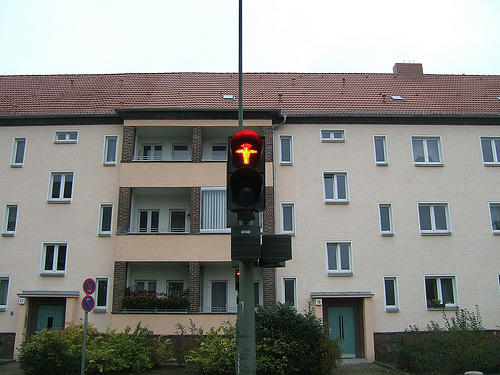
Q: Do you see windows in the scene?
A: Yes, there is a window.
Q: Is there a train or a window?
A: Yes, there is a window.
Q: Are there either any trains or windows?
A: Yes, there is a window.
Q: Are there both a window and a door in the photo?
A: Yes, there are both a window and a door.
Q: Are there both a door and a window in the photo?
A: Yes, there are both a window and a door.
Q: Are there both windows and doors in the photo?
A: Yes, there are both a window and a door.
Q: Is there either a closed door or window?
A: Yes, there is a closed window.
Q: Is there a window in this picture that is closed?
A: Yes, there is a window that is closed.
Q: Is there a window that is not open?
A: Yes, there is an closed window.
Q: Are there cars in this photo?
A: No, there are no cars.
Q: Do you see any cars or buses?
A: No, there are no cars or buses.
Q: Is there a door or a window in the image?
A: Yes, there is a window.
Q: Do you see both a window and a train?
A: No, there is a window but no trains.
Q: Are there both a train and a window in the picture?
A: No, there is a window but no trains.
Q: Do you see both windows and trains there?
A: No, there is a window but no trains.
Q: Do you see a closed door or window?
A: Yes, there is a closed window.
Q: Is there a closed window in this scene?
A: Yes, there is a closed window.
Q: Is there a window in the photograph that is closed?
A: Yes, there is a window that is closed.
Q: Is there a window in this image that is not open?
A: Yes, there is an closed window.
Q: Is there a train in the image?
A: No, there are no trains.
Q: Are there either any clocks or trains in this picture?
A: No, there are no trains or clocks.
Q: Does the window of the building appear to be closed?
A: Yes, the window is closed.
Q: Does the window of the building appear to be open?
A: No, the window is closed.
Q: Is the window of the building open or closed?
A: The window is closed.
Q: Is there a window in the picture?
A: Yes, there is a window.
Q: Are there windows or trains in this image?
A: Yes, there is a window.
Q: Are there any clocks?
A: No, there are no clocks.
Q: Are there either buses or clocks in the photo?
A: No, there are no clocks or buses.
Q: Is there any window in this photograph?
A: Yes, there is a window.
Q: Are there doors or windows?
A: Yes, there is a window.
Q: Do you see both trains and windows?
A: No, there is a window but no trains.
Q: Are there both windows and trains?
A: No, there is a window but no trains.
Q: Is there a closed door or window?
A: Yes, there is a closed window.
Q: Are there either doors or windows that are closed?
A: Yes, the window is closed.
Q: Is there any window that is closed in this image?
A: Yes, there is a closed window.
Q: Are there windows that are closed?
A: Yes, there is a window that is closed.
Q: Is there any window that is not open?
A: Yes, there is an closed window.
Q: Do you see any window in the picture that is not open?
A: Yes, there is an closed window.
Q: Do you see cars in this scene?
A: No, there are no cars.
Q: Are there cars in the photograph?
A: No, there are no cars.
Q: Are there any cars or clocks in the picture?
A: No, there are no cars or clocks.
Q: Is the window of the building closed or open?
A: The window is closed.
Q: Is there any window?
A: Yes, there is a window.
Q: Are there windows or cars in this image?
A: Yes, there is a window.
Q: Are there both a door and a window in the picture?
A: Yes, there are both a window and a door.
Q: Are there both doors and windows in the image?
A: Yes, there are both a window and a door.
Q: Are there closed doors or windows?
A: Yes, there is a closed window.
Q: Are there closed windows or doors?
A: Yes, there is a closed window.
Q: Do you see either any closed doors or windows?
A: Yes, there is a closed window.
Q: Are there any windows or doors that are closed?
A: Yes, the window is closed.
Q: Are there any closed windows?
A: Yes, there is a closed window.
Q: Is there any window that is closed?
A: Yes, there is a window that is closed.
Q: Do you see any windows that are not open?
A: Yes, there is an closed window.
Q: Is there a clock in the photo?
A: No, there are no clocks.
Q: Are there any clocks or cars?
A: No, there are no clocks or cars.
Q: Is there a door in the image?
A: Yes, there is a door.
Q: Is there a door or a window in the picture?
A: Yes, there is a door.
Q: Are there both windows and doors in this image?
A: Yes, there are both a door and a window.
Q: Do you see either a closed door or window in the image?
A: Yes, there is a closed door.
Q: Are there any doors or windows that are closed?
A: Yes, the door is closed.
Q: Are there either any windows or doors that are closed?
A: Yes, the door is closed.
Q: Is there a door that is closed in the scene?
A: Yes, there is a closed door.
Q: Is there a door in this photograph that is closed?
A: Yes, there is a door that is closed.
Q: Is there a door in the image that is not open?
A: Yes, there is an closed door.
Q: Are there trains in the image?
A: No, there are no trains.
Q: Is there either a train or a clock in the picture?
A: No, there are no trains or clocks.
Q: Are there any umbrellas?
A: No, there are no umbrellas.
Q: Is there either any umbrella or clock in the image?
A: No, there are no umbrellas or clocks.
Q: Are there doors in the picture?
A: Yes, there is a door.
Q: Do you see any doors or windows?
A: Yes, there is a door.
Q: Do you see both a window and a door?
A: Yes, there are both a door and a window.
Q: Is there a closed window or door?
A: Yes, there is a closed door.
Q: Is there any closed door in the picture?
A: Yes, there is a closed door.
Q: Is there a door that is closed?
A: Yes, there is a door that is closed.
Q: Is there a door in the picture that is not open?
A: Yes, there is an closed door.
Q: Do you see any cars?
A: No, there are no cars.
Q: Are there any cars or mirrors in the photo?
A: No, there are no cars or mirrors.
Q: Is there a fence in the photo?
A: No, there are no fences.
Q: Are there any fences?
A: No, there are no fences.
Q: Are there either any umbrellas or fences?
A: No, there are no fences or umbrellas.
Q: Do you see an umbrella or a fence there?
A: No, there are no fences or umbrellas.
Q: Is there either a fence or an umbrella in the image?
A: No, there are no fences or umbrellas.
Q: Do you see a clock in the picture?
A: No, there are no clocks.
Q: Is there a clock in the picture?
A: No, there are no clocks.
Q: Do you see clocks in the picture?
A: No, there are no clocks.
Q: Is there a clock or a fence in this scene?
A: No, there are no clocks or fences.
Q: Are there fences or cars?
A: No, there are no fences or cars.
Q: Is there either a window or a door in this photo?
A: Yes, there is a window.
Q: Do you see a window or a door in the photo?
A: Yes, there is a window.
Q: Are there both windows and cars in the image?
A: No, there is a window but no cars.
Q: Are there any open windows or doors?
A: Yes, there is an open window.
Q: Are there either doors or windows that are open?
A: Yes, the window is open.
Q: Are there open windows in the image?
A: Yes, there is an open window.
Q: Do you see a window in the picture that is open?
A: Yes, there is a window that is open.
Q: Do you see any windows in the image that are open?
A: Yes, there is a window that is open.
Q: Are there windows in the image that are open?
A: Yes, there is a window that is open.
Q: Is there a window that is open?
A: Yes, there is a window that is open.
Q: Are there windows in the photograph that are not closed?
A: Yes, there is a open window.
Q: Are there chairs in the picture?
A: No, there are no chairs.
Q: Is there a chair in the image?
A: No, there are no chairs.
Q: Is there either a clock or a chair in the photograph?
A: No, there are no chairs or clocks.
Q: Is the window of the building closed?
A: No, the window is open.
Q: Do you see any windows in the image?
A: Yes, there is a window.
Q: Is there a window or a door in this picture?
A: Yes, there is a window.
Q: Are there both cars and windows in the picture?
A: No, there is a window but no cars.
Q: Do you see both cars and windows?
A: No, there is a window but no cars.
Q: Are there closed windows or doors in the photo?
A: Yes, there is a closed window.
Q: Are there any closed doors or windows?
A: Yes, there is a closed window.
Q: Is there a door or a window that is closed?
A: Yes, the window is closed.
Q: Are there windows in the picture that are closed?
A: Yes, there is a closed window.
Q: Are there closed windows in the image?
A: Yes, there is a closed window.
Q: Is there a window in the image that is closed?
A: Yes, there is a window that is closed.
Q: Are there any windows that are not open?
A: Yes, there is an closed window.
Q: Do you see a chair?
A: No, there are no chairs.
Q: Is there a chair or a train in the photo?
A: No, there are no chairs or trains.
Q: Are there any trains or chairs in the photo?
A: No, there are no chairs or trains.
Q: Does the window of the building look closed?
A: Yes, the window is closed.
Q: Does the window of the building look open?
A: No, the window is closed.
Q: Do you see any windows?
A: Yes, there is a window.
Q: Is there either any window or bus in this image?
A: Yes, there is a window.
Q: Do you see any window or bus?
A: Yes, there is a window.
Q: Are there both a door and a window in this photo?
A: Yes, there are both a window and a door.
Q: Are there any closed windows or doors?
A: Yes, there is a closed window.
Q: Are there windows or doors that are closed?
A: Yes, the window is closed.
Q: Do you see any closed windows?
A: Yes, there is a closed window.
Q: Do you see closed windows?
A: Yes, there is a closed window.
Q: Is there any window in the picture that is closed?
A: Yes, there is a window that is closed.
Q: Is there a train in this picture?
A: No, there are no trains.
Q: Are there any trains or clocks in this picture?
A: No, there are no trains or clocks.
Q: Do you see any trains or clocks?
A: No, there are no trains or clocks.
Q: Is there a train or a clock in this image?
A: No, there are no trains or clocks.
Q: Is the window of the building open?
A: No, the window is closed.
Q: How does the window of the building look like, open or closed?
A: The window is closed.